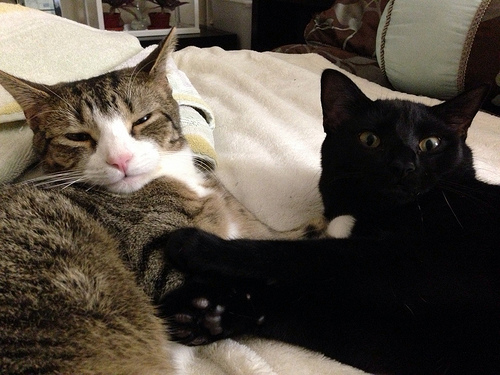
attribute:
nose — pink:
[105, 149, 135, 171]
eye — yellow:
[415, 132, 444, 152]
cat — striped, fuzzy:
[10, 64, 222, 371]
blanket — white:
[190, 59, 316, 166]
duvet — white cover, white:
[0, 1, 499, 373]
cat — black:
[196, 73, 498, 373]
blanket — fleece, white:
[5, 4, 498, 346]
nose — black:
[391, 155, 416, 185]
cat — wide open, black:
[148, 67, 492, 374]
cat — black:
[220, 68, 499, 371]